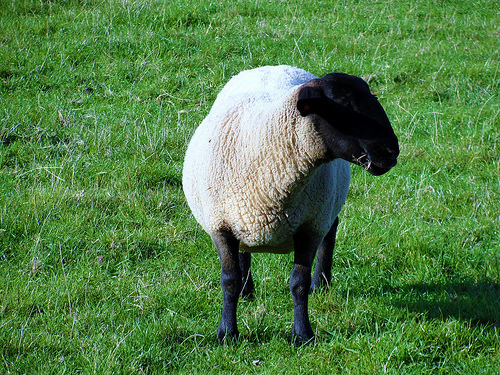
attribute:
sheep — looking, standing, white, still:
[181, 65, 403, 348]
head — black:
[296, 72, 402, 178]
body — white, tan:
[180, 65, 309, 234]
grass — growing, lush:
[353, 152, 376, 181]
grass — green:
[1, 266, 499, 372]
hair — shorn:
[233, 87, 283, 139]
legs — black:
[210, 218, 338, 347]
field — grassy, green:
[2, 2, 496, 373]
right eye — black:
[337, 96, 354, 111]